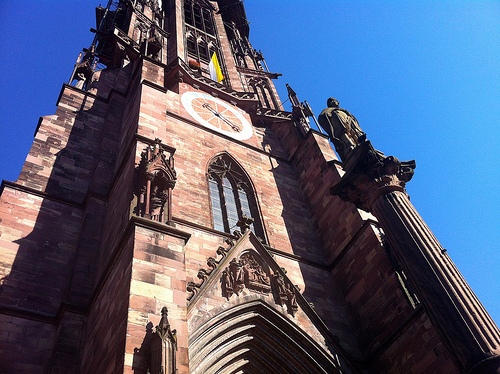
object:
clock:
[181, 91, 259, 142]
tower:
[0, 0, 499, 374]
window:
[207, 150, 267, 244]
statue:
[317, 96, 375, 167]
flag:
[206, 50, 223, 83]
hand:
[221, 116, 241, 133]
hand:
[201, 102, 218, 117]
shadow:
[0, 56, 145, 374]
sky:
[0, 0, 499, 336]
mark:
[55, 83, 64, 106]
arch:
[188, 299, 340, 373]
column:
[341, 178, 500, 372]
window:
[178, 0, 229, 90]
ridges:
[392, 207, 405, 218]